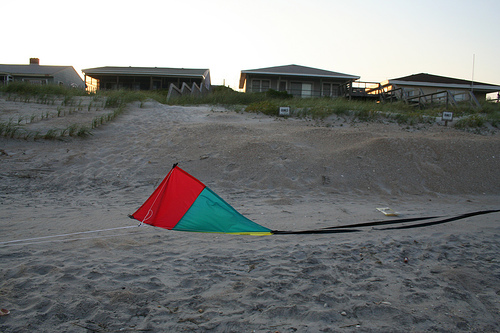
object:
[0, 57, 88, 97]
house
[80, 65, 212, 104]
house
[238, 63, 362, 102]
house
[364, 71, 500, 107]
house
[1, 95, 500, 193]
hill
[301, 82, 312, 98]
window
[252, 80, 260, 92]
window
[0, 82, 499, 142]
grass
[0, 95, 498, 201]
coast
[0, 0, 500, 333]
daytime scene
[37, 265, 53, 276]
footstep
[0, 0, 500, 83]
sky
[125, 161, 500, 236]
kite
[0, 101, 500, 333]
sand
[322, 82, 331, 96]
window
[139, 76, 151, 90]
window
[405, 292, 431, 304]
footstep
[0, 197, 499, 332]
beach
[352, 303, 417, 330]
footstep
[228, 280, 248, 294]
footstep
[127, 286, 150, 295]
footstep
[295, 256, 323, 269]
footstep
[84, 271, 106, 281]
footstep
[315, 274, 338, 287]
footstep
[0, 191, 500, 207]
shoreline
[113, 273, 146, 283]
footstep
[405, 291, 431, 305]
footsep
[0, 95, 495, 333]
ground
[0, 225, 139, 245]
string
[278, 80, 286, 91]
window